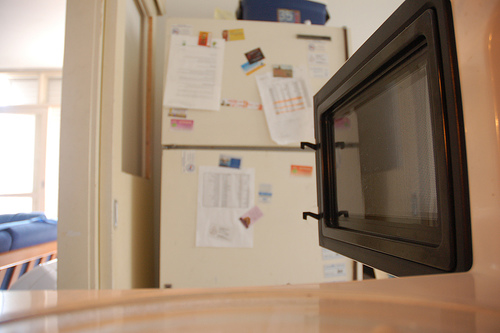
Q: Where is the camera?
A: Inside the microwave.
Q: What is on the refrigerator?
A: Magnets and papers.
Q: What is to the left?
A: A living room with a couch.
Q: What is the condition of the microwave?
A: Very clean with an open door.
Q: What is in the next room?
A: A couch and a window.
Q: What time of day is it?
A: Afternoon.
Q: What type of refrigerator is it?
A: A top-freezer model.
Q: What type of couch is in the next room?
A: A futon with blue cushions.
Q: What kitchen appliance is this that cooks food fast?
A: Microwave.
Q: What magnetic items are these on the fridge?
A: Magnets.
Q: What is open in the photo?
A: Microwave.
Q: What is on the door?
A: Magnets.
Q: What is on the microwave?
A: Window.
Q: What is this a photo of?
A: The kitchen.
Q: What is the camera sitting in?
A: The microwave.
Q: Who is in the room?
A: No one.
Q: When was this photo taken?
A: During the day.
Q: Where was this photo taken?
A: Inside the kitchen.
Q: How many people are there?
A: None.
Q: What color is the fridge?
A: White.